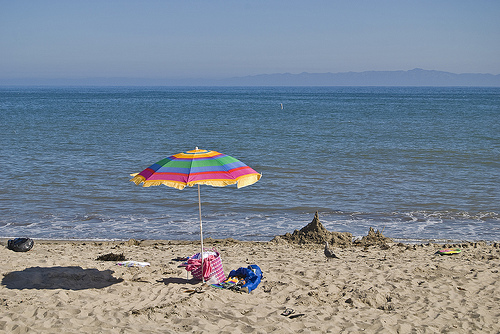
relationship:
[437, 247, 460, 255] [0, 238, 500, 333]
boogie board on top of sand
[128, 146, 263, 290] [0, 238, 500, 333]
umbrella sticking up in sand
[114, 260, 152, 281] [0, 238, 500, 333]
seagull walking on sand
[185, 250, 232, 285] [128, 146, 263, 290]
beach bag under umbrella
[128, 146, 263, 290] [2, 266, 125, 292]
umbrella casting shadow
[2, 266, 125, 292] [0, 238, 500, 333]
shadow on top of sand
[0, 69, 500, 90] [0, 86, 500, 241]
land behind water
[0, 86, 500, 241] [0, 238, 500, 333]
water next to sand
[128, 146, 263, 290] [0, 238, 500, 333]
umbrella upright in sand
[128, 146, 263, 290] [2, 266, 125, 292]
umbrella casts shadow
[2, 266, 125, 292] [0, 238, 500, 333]
shadow located on sand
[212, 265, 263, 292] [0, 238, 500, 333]
backpack on top of sand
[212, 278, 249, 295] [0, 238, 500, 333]
towel on top of sand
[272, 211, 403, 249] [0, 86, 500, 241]
sand castle near water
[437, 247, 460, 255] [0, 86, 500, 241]
boogie board near water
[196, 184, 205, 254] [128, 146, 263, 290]
umbrella pole supporting umbrella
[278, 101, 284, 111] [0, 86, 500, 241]
buoy floating in water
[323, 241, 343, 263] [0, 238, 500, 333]
seagull walking on sand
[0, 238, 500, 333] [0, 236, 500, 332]
sand covering beach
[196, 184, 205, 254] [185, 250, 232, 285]
umbrella pole next to beach bag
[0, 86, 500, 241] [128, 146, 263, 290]
water behind umbrella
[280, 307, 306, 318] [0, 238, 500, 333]
flip flops on top of sand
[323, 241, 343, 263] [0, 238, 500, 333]
seagull on top of sand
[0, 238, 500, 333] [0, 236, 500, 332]
sand on top of beach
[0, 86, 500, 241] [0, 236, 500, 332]
water next to beach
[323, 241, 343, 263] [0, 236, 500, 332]
seagull standing on top of beach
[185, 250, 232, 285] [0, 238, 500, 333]
beach bag on top of sand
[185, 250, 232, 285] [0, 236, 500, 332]
beach bag lying on beach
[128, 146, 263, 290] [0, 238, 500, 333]
umbrella planted on sand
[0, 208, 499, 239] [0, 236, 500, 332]
waves near beach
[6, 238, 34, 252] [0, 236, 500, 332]
object lying on beach